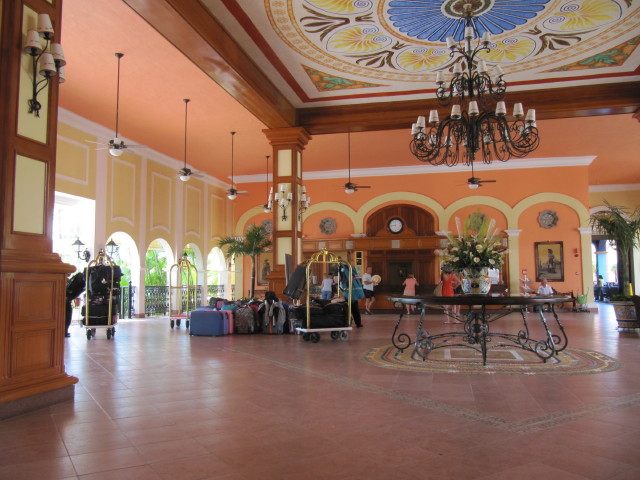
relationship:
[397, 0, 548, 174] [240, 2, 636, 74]
chandelier on ceiling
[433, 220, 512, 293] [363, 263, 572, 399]
plant on a table